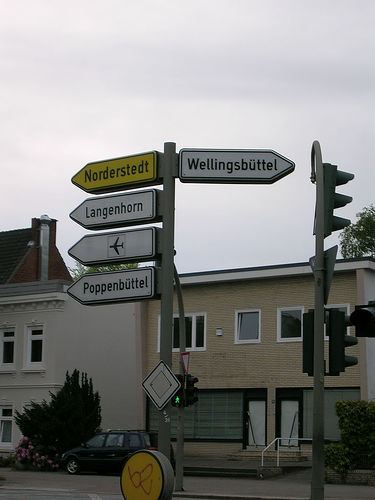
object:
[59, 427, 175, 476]
car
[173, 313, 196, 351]
window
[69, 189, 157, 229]
sign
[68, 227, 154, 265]
sign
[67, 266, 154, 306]
sign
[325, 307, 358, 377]
traffic signals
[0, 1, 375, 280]
sky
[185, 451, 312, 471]
sidewalk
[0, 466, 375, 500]
ground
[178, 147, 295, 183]
sign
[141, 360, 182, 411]
sign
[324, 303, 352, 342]
window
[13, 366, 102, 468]
tree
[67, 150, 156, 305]
four signs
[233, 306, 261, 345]
graffiti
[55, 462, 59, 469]
purple flowers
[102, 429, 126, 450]
windows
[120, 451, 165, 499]
sign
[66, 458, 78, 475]
wheels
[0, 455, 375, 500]
road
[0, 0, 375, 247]
clouds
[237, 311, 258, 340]
window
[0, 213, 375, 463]
building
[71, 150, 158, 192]
sign